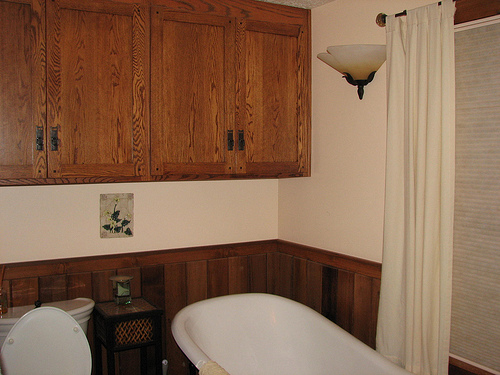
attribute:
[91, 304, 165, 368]
table — little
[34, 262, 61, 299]
paneling — wooden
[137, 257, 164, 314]
paneling — wooden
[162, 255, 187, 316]
paneling — wooden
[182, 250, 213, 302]
paneling — wooden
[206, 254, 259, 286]
paneling — wooden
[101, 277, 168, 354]
table — small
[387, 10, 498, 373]
window — long, white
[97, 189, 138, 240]
artwork — plant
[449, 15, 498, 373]
shade — white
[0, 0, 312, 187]
cabinets — wood grain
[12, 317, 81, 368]
toilet seat — white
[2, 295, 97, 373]
toilet — white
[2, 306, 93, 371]
seat — white, open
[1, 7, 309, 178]
cavinets — tall, oak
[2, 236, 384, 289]
paneling — wood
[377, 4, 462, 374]
curtain — window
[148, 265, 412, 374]
bathtub — white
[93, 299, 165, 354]
table — small, brown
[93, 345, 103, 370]
leg — thin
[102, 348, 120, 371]
leg — thin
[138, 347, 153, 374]
leg — thin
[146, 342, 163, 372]
leg — thin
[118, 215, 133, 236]
leaves — green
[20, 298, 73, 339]
lid — white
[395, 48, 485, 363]
window — bathroom